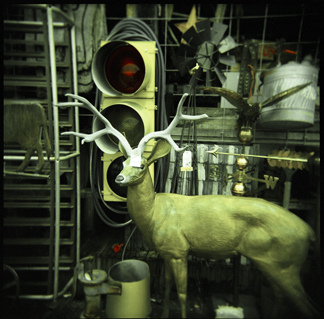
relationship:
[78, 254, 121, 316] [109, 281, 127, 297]
water pump with rust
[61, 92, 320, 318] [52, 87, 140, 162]
deer has antler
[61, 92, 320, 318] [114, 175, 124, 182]
deer has nose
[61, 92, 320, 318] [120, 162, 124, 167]
deer has eye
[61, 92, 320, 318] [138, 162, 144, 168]
deer has eye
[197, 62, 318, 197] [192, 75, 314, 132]
weather vane has metal eagle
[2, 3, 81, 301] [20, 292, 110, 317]
metal rack has wheels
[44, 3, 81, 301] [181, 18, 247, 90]
metal behind windmill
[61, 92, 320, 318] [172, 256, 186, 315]
deer has leg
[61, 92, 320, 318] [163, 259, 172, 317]
deer has leg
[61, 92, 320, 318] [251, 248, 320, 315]
deer has leg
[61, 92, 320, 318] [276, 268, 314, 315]
deer has leg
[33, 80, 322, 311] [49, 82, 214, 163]
deer has antlers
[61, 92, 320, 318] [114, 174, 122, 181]
deer has nose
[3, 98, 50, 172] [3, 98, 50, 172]
cow part cow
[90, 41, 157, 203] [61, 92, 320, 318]
stop light behind deer